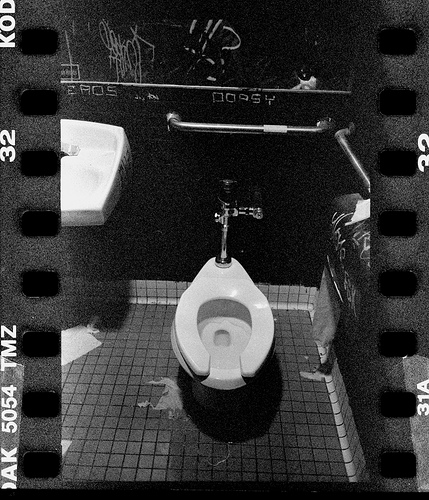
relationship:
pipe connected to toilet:
[215, 171, 261, 264] [168, 239, 275, 392]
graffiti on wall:
[96, 20, 156, 83] [61, 10, 329, 306]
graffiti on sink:
[116, 150, 133, 189] [62, 115, 133, 228]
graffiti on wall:
[327, 209, 371, 312] [54, 21, 379, 273]